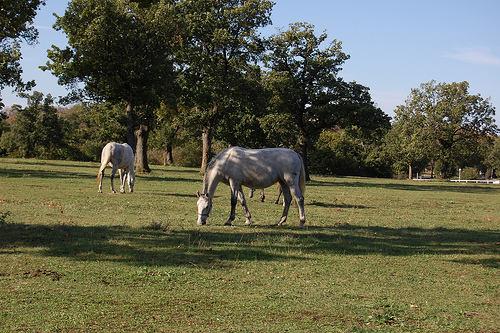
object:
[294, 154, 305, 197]
tail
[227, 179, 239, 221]
leg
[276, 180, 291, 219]
leg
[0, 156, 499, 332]
grass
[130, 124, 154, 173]
trunk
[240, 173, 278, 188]
belly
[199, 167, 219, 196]
neck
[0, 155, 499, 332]
pasture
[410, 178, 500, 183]
fence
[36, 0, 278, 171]
trees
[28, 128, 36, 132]
leaves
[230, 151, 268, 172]
reflections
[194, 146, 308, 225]
horse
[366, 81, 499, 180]
tree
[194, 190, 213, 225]
head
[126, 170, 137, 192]
head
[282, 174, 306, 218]
leg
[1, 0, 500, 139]
sky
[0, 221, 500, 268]
shadows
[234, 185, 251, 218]
legs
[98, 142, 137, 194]
horse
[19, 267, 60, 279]
manure